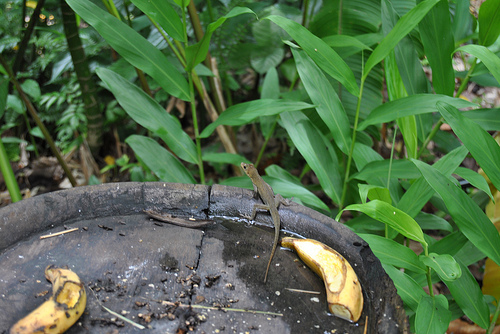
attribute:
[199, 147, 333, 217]
lizard — small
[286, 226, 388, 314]
banana — yellow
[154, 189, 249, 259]
object — wood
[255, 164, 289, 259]
lizard — little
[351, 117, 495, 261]
leaves — green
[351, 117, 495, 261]
weeds — green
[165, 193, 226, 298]
object — black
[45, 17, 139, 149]
trunk — green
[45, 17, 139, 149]
plant — green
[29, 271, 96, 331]
banana — rotten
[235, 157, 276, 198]
eye — black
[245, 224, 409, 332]
banana — yellow, color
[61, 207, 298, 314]
stand — color, black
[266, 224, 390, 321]
banana — ripe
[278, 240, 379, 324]
banana — small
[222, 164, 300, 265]
lizard — green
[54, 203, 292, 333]
stand — black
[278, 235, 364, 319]
banana — yellow, rotting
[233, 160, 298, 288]
lizard — small, gray, sitting, starring, long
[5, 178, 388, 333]
bird bath — wet, gray, old, round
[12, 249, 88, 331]
banana — yellow, rotting, bitten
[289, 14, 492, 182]
leaves — green, lush, healthy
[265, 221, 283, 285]
tail — long, pointed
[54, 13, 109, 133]
trunk — green, thin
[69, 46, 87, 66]
stripes — brown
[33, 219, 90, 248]
stick — brown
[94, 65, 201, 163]
leaf — green, pointed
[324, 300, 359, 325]
banana — white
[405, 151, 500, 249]
leaf — green, pointed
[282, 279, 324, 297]
stick — brown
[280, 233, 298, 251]
stem — yellow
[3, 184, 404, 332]
base — black